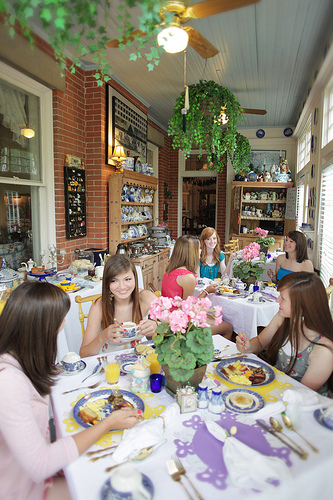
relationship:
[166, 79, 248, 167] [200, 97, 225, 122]
geranium in a pot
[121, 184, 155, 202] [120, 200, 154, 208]
dishes on shelf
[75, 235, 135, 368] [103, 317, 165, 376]
girls eating lunch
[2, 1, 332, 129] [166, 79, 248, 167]
ceiling has vine hanging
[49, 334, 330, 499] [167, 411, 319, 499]
table has silverware setting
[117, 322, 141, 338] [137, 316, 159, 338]
teacup in ladies hand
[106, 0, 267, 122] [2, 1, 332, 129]
fans on ceiling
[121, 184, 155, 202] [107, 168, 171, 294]
beautiful glass in curio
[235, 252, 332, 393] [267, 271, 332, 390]
girl has long brown hair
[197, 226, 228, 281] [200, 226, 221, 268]
girl has red hair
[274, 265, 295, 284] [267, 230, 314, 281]
tube top on girl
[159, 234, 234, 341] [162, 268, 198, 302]
girl in red tanktop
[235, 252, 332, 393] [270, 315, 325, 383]
girl in grey tanktop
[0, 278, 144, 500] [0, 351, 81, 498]
girl in pink shirt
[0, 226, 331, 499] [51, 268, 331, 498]
six girls having breakfast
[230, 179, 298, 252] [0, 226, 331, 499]
breakfast buffet behind girls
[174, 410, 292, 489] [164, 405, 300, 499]
purple decoration on placemat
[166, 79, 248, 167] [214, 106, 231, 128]
plant covering light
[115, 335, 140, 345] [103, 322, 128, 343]
saucer in girls hand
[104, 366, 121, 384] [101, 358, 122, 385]
orange juice in glass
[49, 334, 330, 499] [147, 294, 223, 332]
table has pink flowers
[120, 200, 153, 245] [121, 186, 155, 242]
shelves under dishes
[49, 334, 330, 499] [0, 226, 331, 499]
table with three women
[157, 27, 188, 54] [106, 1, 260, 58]
bright light on fan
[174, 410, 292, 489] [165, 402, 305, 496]
butterflies on place mats